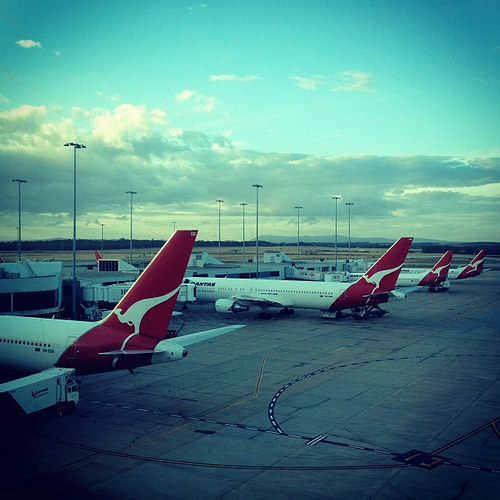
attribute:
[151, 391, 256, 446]
line — dotted, white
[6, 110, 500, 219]
cloud — large, ominous, blue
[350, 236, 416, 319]
tail — white, red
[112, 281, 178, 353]
logo — kangaroo, white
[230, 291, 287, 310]
wing — silver, painted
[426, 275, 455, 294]
truck — white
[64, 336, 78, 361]
door — metal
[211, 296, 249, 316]
engine — red